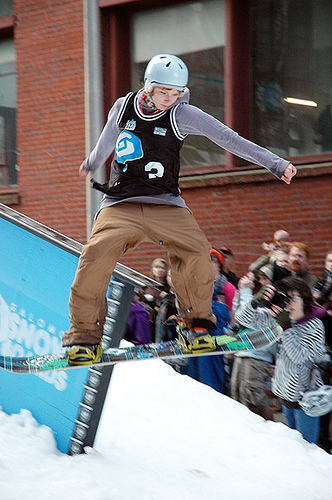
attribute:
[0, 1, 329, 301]
building — brick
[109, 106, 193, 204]
jersey — black, white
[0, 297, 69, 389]
words — white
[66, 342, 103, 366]
left footing — yellow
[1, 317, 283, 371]
snowboard deck — plaid-patterned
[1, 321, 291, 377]
snowboard — black, green, blue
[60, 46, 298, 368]
rider — airborne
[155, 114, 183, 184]
vest — black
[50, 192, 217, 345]
pants — khaki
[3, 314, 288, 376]
snowboard — flat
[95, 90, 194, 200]
jersey — black, white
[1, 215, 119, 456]
wall — blue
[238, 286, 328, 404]
coat — black, white, striped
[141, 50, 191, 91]
helmet — white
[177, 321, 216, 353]
footing — yellow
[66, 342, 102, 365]
footing — yellow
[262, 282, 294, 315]
camera — blacj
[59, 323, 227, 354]
snow boots — yellow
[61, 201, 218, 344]
pants — brown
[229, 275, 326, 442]
person — photographer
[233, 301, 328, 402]
sweater — striped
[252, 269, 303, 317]
camera — black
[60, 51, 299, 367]
snowboarder — airborne